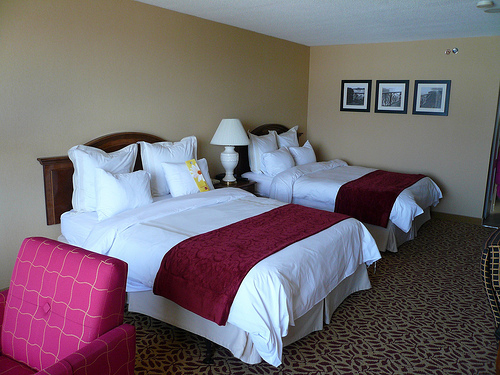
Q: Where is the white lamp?
A: On a table between the beds.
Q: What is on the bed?
A: Covers.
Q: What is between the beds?
A: Lamp.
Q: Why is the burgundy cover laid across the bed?
A: Decor.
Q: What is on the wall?
A: Pictures.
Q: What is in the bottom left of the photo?
A: A chair.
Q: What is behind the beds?
A: Headboards.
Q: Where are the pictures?
A: On the wall.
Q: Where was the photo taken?
A: In a hotel room.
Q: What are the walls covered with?
A: Paint.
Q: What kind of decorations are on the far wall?
A: Pictures.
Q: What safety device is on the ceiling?
A: A smoke detector.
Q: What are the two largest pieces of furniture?
A: Beds.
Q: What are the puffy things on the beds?
A: Pillows.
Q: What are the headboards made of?
A: Wood.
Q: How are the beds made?
A: Neatly.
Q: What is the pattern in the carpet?
A: Floral.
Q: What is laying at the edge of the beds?
A: Runners.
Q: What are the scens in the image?
A: Outdoor scense.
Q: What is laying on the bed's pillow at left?
A: A towel.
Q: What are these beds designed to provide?
A: Comfort.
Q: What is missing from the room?
A: Guests.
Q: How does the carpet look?
A: Clean.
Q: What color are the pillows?
A: White.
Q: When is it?
A: Day time.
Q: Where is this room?
A: In a hotel.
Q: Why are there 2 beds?
A: For more people to sleep.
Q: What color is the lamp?
A: White.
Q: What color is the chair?
A: Red.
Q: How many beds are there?
A: 2.